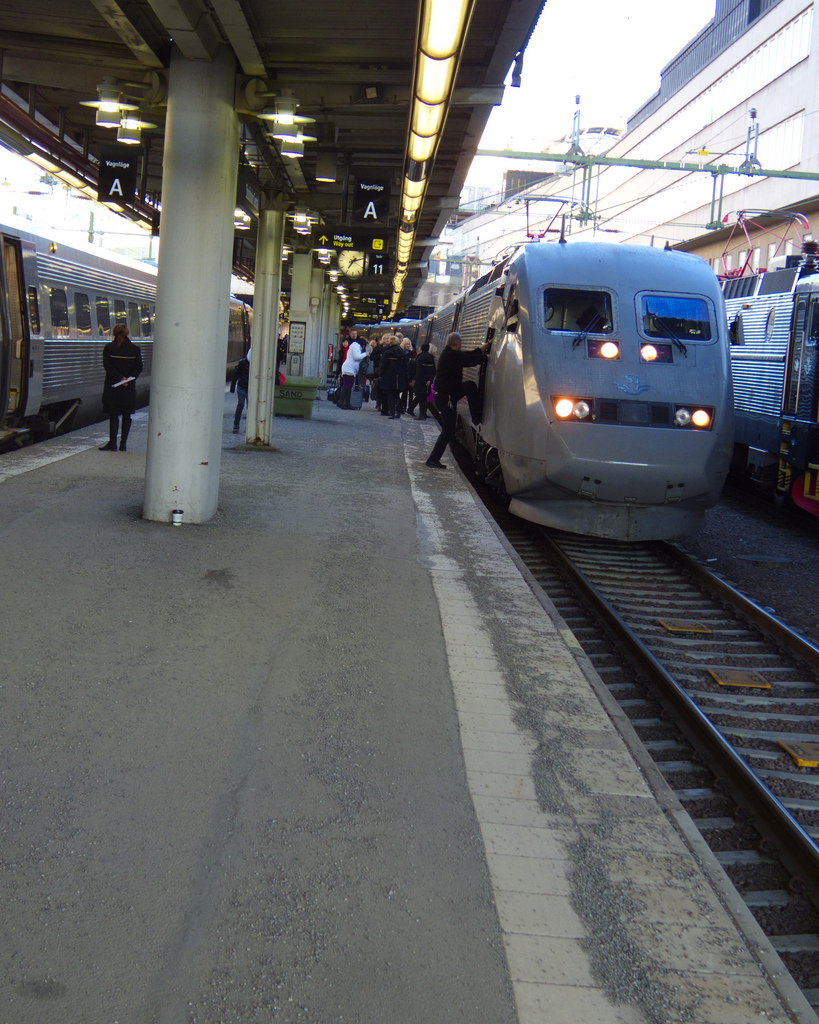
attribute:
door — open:
[429, 254, 546, 498]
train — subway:
[2, 235, 362, 467]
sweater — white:
[342, 339, 371, 376]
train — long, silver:
[387, 247, 723, 564]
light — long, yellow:
[389, 162, 423, 316]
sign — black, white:
[340, 174, 395, 230]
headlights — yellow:
[545, 390, 717, 437]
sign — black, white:
[341, 163, 396, 216]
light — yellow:
[371, 2, 485, 340]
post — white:
[142, 78, 256, 514]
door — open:
[5, 233, 37, 423]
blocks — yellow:
[651, 607, 779, 703]